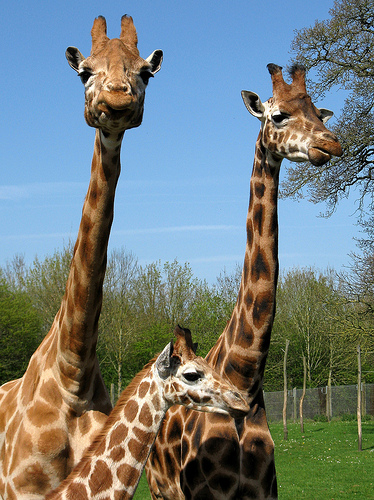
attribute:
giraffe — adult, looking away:
[143, 63, 342, 499]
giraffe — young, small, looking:
[41, 324, 250, 500]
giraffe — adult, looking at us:
[0, 14, 163, 500]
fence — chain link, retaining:
[262, 383, 373, 423]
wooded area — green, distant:
[0, 235, 373, 450]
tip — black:
[289, 64, 306, 74]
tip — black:
[267, 63, 281, 75]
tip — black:
[182, 327, 192, 334]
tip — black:
[174, 324, 184, 336]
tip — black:
[121, 14, 132, 23]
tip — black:
[94, 14, 106, 22]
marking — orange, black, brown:
[253, 181, 265, 200]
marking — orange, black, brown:
[251, 202, 265, 236]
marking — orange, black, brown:
[249, 244, 271, 284]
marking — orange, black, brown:
[252, 289, 273, 330]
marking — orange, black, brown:
[243, 289, 253, 312]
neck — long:
[203, 141, 282, 400]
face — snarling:
[77, 55, 155, 128]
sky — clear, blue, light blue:
[0, 1, 373, 322]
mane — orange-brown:
[43, 351, 161, 499]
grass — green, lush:
[132, 414, 373, 499]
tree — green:
[277, 0, 373, 218]